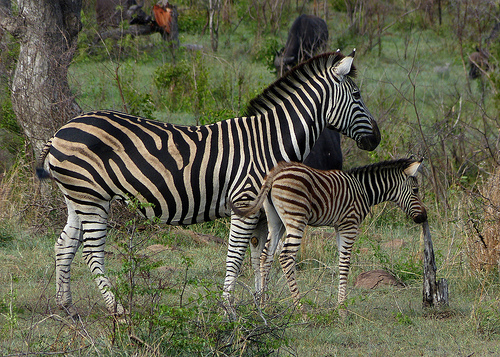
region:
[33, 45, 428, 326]
Two zebras in a field.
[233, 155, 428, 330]
A young zebra with its mother.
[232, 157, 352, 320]
The rear body of the young zebra is striped with brown, tan and white colors.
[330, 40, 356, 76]
The adult zebra's ears are white and pointing forward.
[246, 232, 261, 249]
Zebra with a round brown patch on the left front leg.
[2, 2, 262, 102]
The background of the area is bushy.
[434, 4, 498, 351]
Dry branches near the zebras.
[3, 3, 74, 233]
Tall standing old tree.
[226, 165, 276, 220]
Young zebra with a long brown and white tail.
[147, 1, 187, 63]
A tree with an open trunk.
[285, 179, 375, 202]
A zebra foal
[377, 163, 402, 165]
The mane on the foal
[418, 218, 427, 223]
Mouth against a tree stump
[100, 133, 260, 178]
An adult zebra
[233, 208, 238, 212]
Hairs on the small tail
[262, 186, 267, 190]
The tail of the foal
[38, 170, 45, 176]
Dark black hairs on the tail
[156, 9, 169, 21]
A tree stripped off its bark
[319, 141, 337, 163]
Buffalo visible below the zebra head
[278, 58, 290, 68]
A buffalo grazing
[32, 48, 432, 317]
zebras in the forest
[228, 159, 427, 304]
Baby zebra beside mother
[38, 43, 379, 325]
Mother zebra beside baby zebra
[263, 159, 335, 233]
Black and brown stripes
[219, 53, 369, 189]
White and black stripes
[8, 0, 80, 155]
Tree trunk in forest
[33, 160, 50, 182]
Black tip of zebras tail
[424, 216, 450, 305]
Small gray tree trunk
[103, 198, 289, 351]
Green bush in forest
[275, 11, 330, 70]
Black animal in the forest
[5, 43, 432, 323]
An adult and baby zebra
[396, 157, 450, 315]
baby zebra investigates a small broken tree trunk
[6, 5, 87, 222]
a curved tree trunk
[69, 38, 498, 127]
deep brush and young trees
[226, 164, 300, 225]
baby zebra tail tuned up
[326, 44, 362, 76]
white ear with black at the tip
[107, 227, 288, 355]
scraggly bush in foreground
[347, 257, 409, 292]
a larger rock in the grass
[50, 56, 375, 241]
stripes on zebra go under the stomach on the Plains variety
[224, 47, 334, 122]
short brushy striped mane